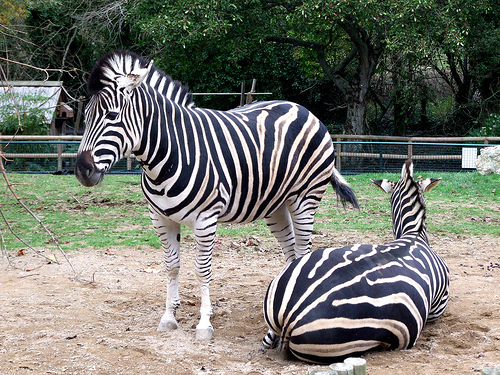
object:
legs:
[148, 199, 182, 331]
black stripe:
[266, 181, 451, 364]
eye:
[104, 111, 120, 121]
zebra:
[74, 50, 359, 341]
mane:
[88, 49, 196, 108]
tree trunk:
[323, 32, 378, 168]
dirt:
[1, 237, 498, 375]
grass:
[3, 171, 500, 252]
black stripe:
[82, 73, 339, 286]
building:
[0, 79, 73, 174]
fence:
[2, 141, 498, 174]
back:
[286, 102, 337, 204]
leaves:
[0, 0, 483, 92]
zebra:
[261, 159, 450, 366]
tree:
[0, 4, 499, 144]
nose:
[74, 165, 95, 178]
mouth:
[75, 172, 104, 187]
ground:
[0, 173, 500, 371]